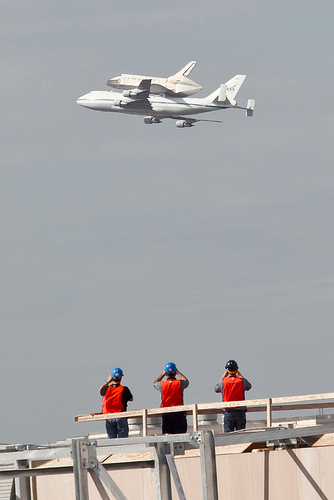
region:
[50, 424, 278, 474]
silver iron posts against the wall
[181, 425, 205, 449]
silver studs in the post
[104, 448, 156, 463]
pattern on pink wood surface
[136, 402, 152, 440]
post in wooden surface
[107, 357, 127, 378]
shiny blue helmet on man's head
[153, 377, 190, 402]
man wearing orange shirt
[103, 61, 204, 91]
space shuttle atop jumbo jet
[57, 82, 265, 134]
large white and blue jet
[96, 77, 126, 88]
gray nose on space shuttle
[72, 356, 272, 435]
men watching space shuttle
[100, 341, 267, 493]
3 guys in orange vest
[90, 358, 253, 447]
three men working outside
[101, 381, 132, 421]
a bright orange vest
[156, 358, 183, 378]
a blue hardhat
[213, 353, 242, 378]
a black hardhat on a man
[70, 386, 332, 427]
a thin railing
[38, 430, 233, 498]
metal structure pieces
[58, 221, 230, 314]
a pale gray sky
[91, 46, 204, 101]
a small airplane in the sky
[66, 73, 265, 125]
a large air plane in the sky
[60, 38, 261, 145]
two airplanes flying with each other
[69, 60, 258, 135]
the shuttle is on the plane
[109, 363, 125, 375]
the hardhat is blue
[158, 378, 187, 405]
the vest is red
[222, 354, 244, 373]
the hard hat is black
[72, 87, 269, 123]
the plane is flying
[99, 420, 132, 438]
the jeans are blue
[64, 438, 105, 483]
the scaffle is metal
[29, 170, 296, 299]
the sky is dreary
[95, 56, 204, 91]
the shuttle is white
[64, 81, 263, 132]
the airplane is big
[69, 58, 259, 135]
a rocket ship carried on the back of a plane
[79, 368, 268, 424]
three men watching the plane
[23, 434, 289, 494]
a large area of metal poles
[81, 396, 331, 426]
a long metal railing behind three men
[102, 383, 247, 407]
red vests on three men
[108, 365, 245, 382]
blue safety helmets on three men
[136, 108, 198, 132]
the landing gear on the plane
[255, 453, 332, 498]
the shadows of two metal poles on the wall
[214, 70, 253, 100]
the white tail fin of the airplane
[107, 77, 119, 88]
the black nose of the rocket ship